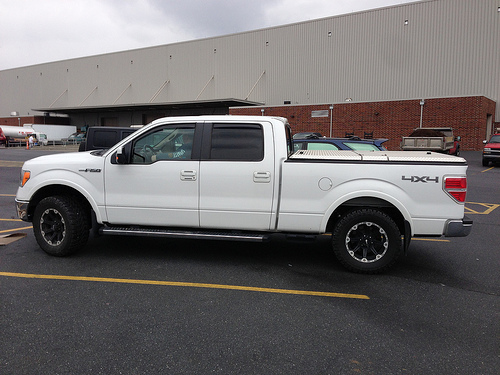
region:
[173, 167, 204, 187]
door handle on white truck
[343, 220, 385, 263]
white rim on truck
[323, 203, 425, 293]
large black truck wheel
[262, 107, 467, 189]
extended cab on back of truck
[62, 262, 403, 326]
yellow line in the parking lot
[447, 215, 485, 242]
gray bumper on truck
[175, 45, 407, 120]
tall gray and brown building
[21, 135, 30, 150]
orange cone on ground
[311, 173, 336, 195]
round gas compartment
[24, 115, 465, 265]
large white truck in spoit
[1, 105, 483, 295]
white 4x4 pickup truck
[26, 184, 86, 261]
truck's front tire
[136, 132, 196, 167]
person sitting in the truck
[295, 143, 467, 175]
cover on the truck bed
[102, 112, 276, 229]
two side doors on the truck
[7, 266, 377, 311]
yellow parking space line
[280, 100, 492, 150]
red brick building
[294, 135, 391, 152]
blue station wagon next to the truck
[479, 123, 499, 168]
front of a red truck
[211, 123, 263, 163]
rear side window is tinted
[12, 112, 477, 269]
A parked white truck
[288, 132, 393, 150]
a parked blue car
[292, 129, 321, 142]
a parked black car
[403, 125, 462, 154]
a large red truck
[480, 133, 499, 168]
a large red truck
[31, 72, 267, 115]
a large metal awning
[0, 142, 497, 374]
an asphalt road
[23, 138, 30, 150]
an orange traffic cone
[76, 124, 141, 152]
a parked black car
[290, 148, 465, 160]
a metal truck bed cover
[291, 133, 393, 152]
A parked blue car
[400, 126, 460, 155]
a parked red truck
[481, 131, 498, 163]
a parked red truck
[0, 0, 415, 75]
A grey cloudy sky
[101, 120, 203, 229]
a white car door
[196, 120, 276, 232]
a white car door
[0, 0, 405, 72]
gray cloud in sky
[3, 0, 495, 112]
wall of industrial building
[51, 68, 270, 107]
row of poles on building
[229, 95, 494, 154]
brick wall on building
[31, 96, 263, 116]
awning suspended by poles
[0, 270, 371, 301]
yellow line on asphalt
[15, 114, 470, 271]
side of white truck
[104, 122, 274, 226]
two doors on truck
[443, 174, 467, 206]
red light on truck bed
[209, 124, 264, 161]
dark tinted truck window